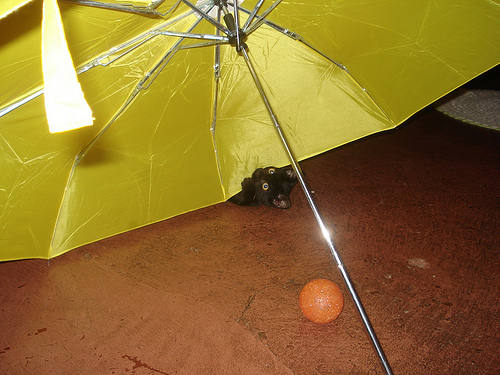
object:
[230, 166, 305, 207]
cat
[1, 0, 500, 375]
umbrella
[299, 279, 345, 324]
ball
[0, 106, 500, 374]
ground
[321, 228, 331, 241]
light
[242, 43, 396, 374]
handle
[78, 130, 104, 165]
shadow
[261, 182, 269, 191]
eyes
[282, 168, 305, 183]
ear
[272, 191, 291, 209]
ear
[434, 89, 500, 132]
mat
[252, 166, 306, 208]
head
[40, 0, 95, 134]
frame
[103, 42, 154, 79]
wrinkles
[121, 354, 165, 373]
spots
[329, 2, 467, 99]
corner